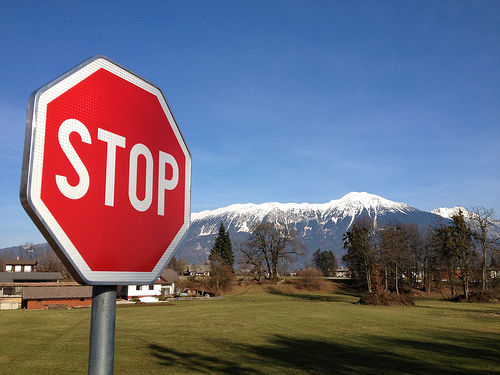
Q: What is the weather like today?
A: It is cloudless.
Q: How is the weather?
A: It is cloudless.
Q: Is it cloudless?
A: Yes, it is cloudless.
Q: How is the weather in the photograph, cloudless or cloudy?
A: It is cloudless.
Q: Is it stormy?
A: No, it is cloudless.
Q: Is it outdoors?
A: Yes, it is outdoors.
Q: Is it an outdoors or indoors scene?
A: It is outdoors.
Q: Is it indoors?
A: No, it is outdoors.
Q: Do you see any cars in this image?
A: No, there are no cars.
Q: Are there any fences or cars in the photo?
A: No, there are no cars or fences.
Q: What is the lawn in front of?
A: The lawn is in front of the buildings.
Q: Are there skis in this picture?
A: No, there are no skis.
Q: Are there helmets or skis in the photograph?
A: No, there are no skis or helmets.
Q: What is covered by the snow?
A: The mountain is covered by the snow.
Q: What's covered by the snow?
A: The mountain is covered by the snow.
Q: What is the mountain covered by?
A: The mountain is covered by the snow.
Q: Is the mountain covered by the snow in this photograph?
A: Yes, the mountain is covered by the snow.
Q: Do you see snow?
A: Yes, there is snow.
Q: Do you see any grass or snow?
A: Yes, there is snow.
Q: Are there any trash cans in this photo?
A: No, there are no trash cans.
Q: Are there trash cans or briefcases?
A: No, there are no trash cans or briefcases.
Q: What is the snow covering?
A: The snow is covering the mountain.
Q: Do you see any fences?
A: No, there are no fences.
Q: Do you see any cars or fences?
A: No, there are no fences or cars.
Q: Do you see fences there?
A: No, there are no fences.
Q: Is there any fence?
A: No, there are no fences.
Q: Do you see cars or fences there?
A: No, there are no fences or cars.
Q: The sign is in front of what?
A: The sign is in front of the buildings.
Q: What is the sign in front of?
A: The sign is in front of the buildings.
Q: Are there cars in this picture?
A: No, there are no cars.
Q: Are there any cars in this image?
A: No, there are no cars.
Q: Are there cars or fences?
A: No, there are no cars or fences.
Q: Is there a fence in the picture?
A: No, there are no fences.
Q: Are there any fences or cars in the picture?
A: No, there are no fences or cars.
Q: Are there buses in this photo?
A: No, there are no buses.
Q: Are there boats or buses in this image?
A: No, there are no buses or boats.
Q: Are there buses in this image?
A: No, there are no buses.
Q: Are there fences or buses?
A: No, there are no buses or fences.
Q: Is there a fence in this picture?
A: No, there are no fences.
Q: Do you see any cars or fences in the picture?
A: No, there are no fences or cars.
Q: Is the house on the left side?
A: Yes, the house is on the left of the image.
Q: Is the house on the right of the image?
A: No, the house is on the left of the image.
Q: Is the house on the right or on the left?
A: The house is on the left of the image.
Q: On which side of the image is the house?
A: The house is on the left of the image.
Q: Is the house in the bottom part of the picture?
A: Yes, the house is in the bottom of the image.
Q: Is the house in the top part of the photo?
A: No, the house is in the bottom of the image.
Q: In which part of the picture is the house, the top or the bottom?
A: The house is in the bottom of the image.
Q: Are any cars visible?
A: No, there are no cars.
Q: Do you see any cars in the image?
A: No, there are no cars.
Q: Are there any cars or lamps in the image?
A: No, there are no cars or lamps.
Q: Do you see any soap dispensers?
A: No, there are no soap dispensers.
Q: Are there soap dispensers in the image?
A: No, there are no soap dispensers.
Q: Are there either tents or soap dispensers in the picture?
A: No, there are no soap dispensers or tents.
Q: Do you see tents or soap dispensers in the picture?
A: No, there are no soap dispensers or tents.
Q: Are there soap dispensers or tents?
A: No, there are no soap dispensers or tents.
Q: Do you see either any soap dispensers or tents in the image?
A: No, there are no soap dispensers or tents.